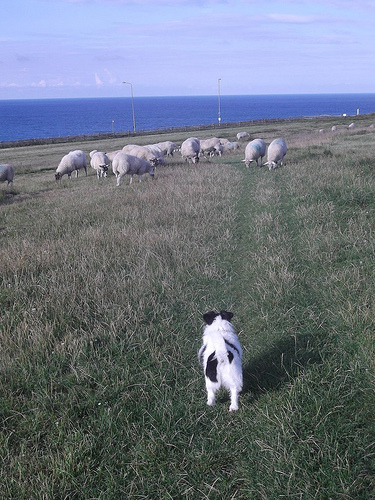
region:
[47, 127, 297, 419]
A dog herding sheep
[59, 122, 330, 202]
sheep are in the field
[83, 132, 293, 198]
the sheep are grazing together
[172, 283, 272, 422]
a cat is walking towrad the sheep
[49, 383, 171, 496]
the floor is coverd of grsses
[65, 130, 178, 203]
the sheep are white in color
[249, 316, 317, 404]
cat shadow is on the field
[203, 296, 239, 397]
the cat is black and white in color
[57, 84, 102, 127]
the ocean water is blue incolor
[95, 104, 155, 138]
the fild is near the ocean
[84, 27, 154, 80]
the sky is clear blue in color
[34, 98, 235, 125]
calm ocean waters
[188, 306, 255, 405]
black and white dog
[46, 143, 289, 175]
many sheep grazing in the grass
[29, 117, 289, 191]
many sheep in the grass by ocean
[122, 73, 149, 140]
light post by the ocean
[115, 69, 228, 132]
two tall light posts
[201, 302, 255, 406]
white dog with black spots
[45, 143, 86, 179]
sheep grazing in the grass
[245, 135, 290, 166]
two sheep in the grass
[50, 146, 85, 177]
a sheep in the grass near the ocean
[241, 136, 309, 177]
two sheep grazing in a field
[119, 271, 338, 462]
a black and white dog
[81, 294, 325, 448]
a black and white sheepdog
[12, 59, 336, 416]
sheep and the dog that herds them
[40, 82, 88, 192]
a sheep grazing by water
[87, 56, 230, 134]
two lamp posts on the coast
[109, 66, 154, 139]
a lamp post near the coast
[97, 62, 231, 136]
two lamp posts near the coastline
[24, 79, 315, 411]
a dog herding sheep near water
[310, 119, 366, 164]
three sheep in the distance